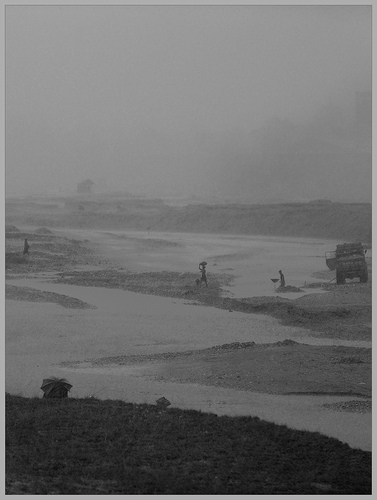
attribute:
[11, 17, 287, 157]
sky — blue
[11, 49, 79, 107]
clouds — white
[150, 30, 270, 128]
sky — blue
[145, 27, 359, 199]
sky — blue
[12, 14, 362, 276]
sky — blue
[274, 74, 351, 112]
clouds — white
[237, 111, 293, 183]
clouds — white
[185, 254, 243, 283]
human — walking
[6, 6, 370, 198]
clouds — white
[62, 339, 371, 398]
land — flat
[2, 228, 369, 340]
land — flat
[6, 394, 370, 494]
land — flat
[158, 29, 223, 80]
cloud — white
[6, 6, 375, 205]
sky — blue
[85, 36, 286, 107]
sky — blue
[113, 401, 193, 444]
cow — black, white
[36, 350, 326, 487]
grass — green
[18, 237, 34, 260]
person — walking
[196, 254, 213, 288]
human — walking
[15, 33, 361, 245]
sky — blue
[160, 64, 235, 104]
clouds — white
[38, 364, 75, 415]
persons — sitting